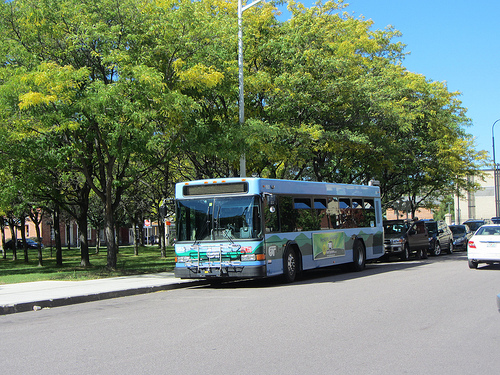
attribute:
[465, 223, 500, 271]
vehicle — white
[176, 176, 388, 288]
bus — blue, parked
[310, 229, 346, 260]
advertisement — green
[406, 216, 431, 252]
door — open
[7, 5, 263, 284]
tree — large, green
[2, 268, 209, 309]
sidewalk — white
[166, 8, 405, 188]
tree — green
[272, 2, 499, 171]
sky — blue, clear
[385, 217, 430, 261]
car — parallel parked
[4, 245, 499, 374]
road — gray, asphalt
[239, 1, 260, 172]
light post — silver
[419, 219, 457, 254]
car — parked